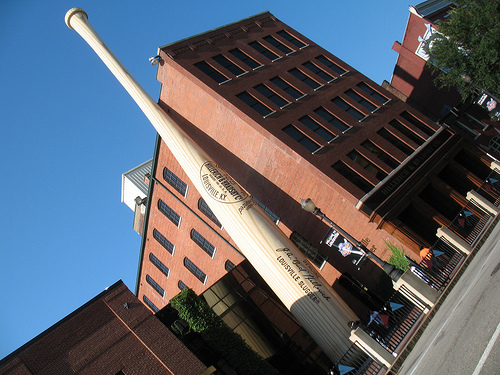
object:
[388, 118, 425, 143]
window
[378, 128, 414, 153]
window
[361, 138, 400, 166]
window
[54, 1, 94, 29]
knob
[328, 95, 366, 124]
windows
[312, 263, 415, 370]
shadow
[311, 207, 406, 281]
lamp post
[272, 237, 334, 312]
writing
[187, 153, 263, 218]
label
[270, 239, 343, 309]
label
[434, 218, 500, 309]
street lamp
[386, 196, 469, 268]
gate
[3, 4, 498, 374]
picture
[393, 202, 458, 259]
doorway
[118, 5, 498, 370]
building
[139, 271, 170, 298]
windows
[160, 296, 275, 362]
vine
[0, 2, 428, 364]
sky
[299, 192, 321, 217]
lamp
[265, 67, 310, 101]
window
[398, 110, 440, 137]
window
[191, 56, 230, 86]
window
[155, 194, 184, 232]
window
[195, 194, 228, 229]
window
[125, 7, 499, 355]
museum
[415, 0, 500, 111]
tree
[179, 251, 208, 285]
windows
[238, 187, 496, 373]
fence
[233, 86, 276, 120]
windows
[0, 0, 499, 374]
world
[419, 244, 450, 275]
people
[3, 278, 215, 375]
building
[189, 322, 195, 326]
leaves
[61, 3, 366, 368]
bat